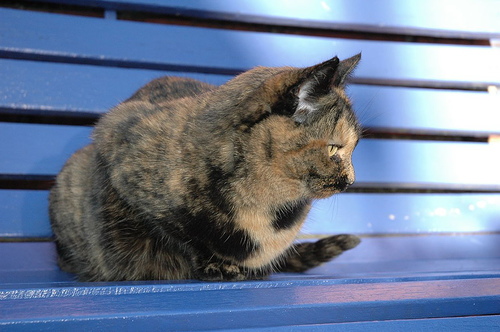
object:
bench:
[4, 2, 496, 326]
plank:
[0, 7, 492, 89]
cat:
[47, 52, 363, 282]